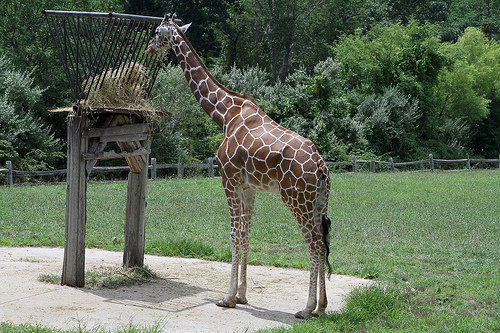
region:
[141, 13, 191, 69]
Zebra eating hay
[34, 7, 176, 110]
Black feeding bin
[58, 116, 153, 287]
Wood stand supporting giraffe feeding cage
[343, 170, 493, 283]
A green grassy meadow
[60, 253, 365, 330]
Concrete pad underneath giraffe's feet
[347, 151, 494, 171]
Weathered wooden fence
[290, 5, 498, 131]
Forest of bushes and trees in background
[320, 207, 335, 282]
Curly long black tail of giraffe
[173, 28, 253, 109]
Short brown mane of giraffe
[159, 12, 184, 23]
Short black horns on giraffe's head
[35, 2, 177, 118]
Hay in a basket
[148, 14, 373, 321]
Giraffe eating hay out of the basket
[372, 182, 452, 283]
Short green grass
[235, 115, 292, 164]
Spots that are brown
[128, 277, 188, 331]
Sand in the middle of the grass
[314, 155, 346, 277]
Fuzzy tail of giraffe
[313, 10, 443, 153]
Trees in the woods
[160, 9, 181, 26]
Horns on the top of the giraffe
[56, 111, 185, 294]
Wooden poles holding hay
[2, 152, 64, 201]
Wooden fence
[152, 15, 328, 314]
the tall giraffe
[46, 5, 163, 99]
the metal part of the giraffe feeder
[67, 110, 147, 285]
the wooden post of the giraffe feeder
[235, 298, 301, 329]
the small shadow from the giraffe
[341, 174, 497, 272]
the short green grass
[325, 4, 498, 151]
the tall green trees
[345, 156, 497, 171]
the wooden fence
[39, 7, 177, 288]
the entire structure of the feeder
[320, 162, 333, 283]
the giraffes long tail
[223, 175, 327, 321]
the legs of the giraffe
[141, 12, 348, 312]
The giraffe is standing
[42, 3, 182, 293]
Tall wooden and metal feeder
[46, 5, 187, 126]
The feeder is filled with hay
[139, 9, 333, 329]
The giraffe is brown and white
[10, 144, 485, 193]
A low wooden fence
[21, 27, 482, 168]
Trees and bushes behind the fence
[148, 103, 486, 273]
A green grass field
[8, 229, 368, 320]
A rectangular dirt patch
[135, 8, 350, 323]
The giraffe is eating hay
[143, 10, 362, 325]
The giraffe is standing on dirt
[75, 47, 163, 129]
a container of hay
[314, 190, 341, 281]
black giraffe tail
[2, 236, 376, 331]
cement slab on the ground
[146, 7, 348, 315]
giraffe eating hay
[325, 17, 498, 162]
green trees in the woods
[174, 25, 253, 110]
giraffe's brown mane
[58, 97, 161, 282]
small wooden food stand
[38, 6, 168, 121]
metal food container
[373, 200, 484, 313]
green and brown grass with weeds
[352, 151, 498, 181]
wooden fence around the field